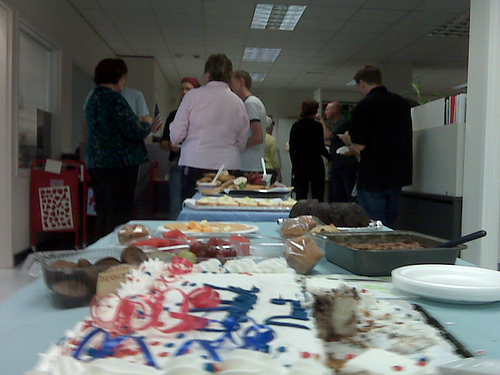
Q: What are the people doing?
A: Celebrating.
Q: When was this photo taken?
A: During a party.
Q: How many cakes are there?
A: One.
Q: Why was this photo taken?
A: To show the party.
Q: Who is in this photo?
A: People attending the party.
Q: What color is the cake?
A: Red, white and blue.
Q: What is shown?
A: Food on a table.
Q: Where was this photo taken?
A: Inside a building.